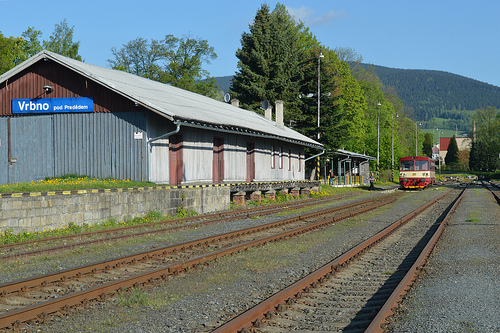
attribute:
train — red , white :
[367, 116, 455, 240]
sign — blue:
[8, 74, 127, 145]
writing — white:
[16, 99, 89, 110]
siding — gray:
[1, 110, 149, 186]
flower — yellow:
[46, 177, 48, 179]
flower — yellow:
[67, 180, 70, 182]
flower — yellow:
[95, 177, 98, 179]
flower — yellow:
[106, 180, 108, 181]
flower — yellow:
[30, 180, 34, 183]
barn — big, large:
[0, 46, 327, 186]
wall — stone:
[1, 179, 231, 236]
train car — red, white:
[397, 153, 437, 189]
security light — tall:
[315, 49, 325, 144]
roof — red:
[438, 135, 463, 149]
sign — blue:
[10, 96, 93, 114]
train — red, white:
[393, 157, 442, 191]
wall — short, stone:
[4, 177, 236, 244]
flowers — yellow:
[28, 170, 148, 191]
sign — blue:
[8, 88, 95, 118]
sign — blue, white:
[8, 95, 97, 118]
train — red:
[393, 141, 436, 190]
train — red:
[395, 150, 436, 190]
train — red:
[402, 154, 440, 195]